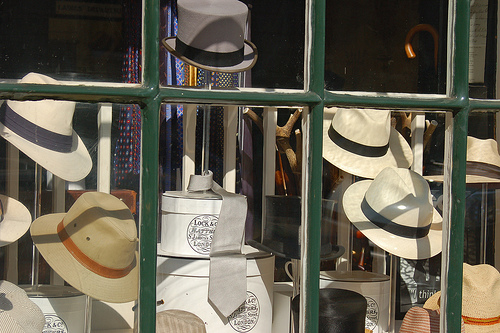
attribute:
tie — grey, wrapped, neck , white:
[188, 167, 251, 322]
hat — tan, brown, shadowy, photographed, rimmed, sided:
[30, 190, 144, 304]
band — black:
[361, 194, 432, 238]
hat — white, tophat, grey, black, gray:
[162, 0, 258, 73]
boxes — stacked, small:
[157, 189, 278, 332]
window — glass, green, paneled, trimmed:
[155, 101, 308, 332]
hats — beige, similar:
[301, 99, 448, 259]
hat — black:
[243, 192, 347, 264]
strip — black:
[0, 102, 75, 153]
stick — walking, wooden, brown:
[403, 17, 443, 90]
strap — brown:
[58, 218, 138, 284]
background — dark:
[2, 1, 500, 105]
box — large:
[150, 250, 276, 332]